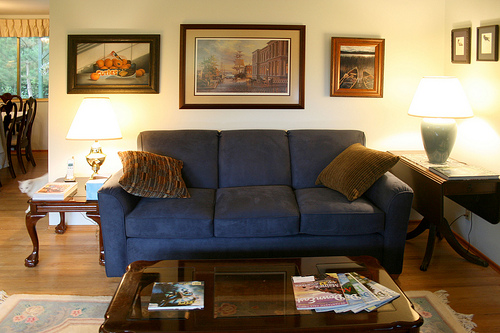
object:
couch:
[98, 129, 415, 278]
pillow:
[116, 150, 192, 198]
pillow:
[315, 142, 400, 203]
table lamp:
[63, 96, 124, 180]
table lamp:
[407, 76, 473, 165]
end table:
[24, 176, 112, 268]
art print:
[178, 24, 305, 109]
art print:
[65, 34, 161, 94]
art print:
[329, 36, 385, 98]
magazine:
[290, 272, 349, 310]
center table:
[100, 254, 424, 332]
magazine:
[147, 281, 204, 312]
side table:
[384, 150, 499, 272]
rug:
[0, 289, 479, 332]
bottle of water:
[66, 154, 76, 182]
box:
[85, 183, 100, 201]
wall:
[24, 3, 47, 247]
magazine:
[349, 273, 392, 314]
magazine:
[350, 272, 401, 313]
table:
[0, 111, 29, 135]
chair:
[0, 92, 24, 133]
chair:
[10, 96, 37, 174]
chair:
[0, 102, 18, 181]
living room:
[0, 0, 499, 332]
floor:
[0, 175, 499, 332]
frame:
[450, 28, 471, 64]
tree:
[20, 37, 49, 98]